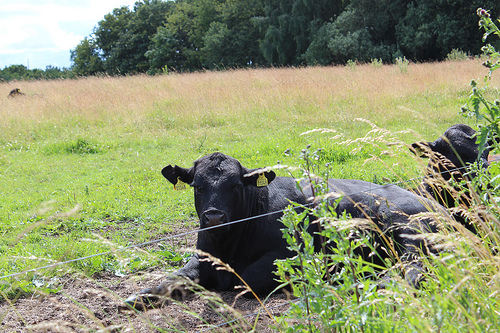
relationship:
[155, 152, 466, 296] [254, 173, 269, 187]
cow has tag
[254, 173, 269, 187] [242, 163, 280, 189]
tag in ear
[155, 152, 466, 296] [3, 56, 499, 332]
cow laying in pasture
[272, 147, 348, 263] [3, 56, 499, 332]
flowers growing in pasture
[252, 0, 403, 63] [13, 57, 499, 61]
trees in background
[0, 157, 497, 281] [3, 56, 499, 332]
wire along pasture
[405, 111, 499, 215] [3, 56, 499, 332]
cow in pasture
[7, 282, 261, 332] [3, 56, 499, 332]
dirt in pasture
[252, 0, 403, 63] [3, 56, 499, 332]
trees in pasture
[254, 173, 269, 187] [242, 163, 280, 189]
tag on ear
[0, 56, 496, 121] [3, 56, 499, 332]
grass on pasture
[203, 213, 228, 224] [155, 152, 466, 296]
nostrils of cow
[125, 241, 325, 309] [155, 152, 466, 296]
legs on side of cow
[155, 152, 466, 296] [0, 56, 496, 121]
cow lies on grass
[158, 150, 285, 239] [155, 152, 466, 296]
head of cow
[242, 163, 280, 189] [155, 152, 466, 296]
ear of cow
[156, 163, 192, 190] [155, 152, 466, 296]
ear of cow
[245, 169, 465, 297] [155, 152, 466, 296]
body of cow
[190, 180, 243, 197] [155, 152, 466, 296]
eyes of cow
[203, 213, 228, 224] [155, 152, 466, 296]
nostrils on cow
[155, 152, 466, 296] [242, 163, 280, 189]
cow has ear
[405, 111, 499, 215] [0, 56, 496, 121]
cow in grass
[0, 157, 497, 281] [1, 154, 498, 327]
wire of fence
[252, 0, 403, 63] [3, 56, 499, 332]
trees beyond pasture